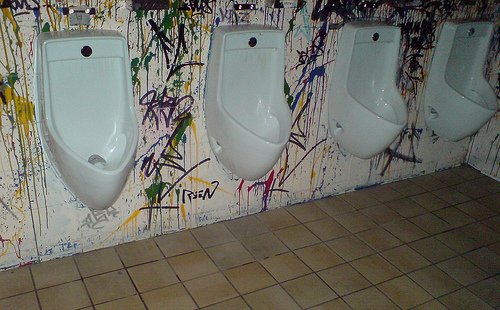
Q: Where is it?
A: This is at the restroom.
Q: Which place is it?
A: It is a restroom.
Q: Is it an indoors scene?
A: Yes, it is indoors.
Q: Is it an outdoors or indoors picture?
A: It is indoors.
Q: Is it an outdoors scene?
A: No, it is indoors.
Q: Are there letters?
A: Yes, there are letters.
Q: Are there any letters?
A: Yes, there are letters.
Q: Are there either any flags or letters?
A: Yes, there are letters.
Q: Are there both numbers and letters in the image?
A: No, there are letters but no numbers.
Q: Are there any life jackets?
A: No, there are no life jackets.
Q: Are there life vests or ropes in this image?
A: No, there are no life vests or ropes.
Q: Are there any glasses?
A: No, there are no glasses.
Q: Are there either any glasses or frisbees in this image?
A: No, there are no glasses or frisbees.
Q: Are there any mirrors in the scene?
A: No, there are no mirrors.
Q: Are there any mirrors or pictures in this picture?
A: No, there are no mirrors or pictures.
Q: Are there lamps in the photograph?
A: No, there are no lamps.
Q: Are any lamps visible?
A: No, there are no lamps.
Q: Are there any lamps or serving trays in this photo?
A: No, there are no lamps or serving trays.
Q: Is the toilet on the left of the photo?
A: Yes, the toilet is on the left of the image.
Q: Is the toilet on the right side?
A: No, the toilet is on the left of the image.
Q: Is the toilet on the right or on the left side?
A: The toilet is on the left of the image.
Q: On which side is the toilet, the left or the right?
A: The toilet is on the left of the image.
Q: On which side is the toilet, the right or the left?
A: The toilet is on the left of the image.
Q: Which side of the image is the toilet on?
A: The toilet is on the left of the image.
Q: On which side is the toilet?
A: The toilet is on the left of the image.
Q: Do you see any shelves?
A: No, there are no shelves.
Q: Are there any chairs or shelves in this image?
A: No, there are no shelves or chairs.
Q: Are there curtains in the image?
A: No, there are no curtains.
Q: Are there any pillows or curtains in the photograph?
A: No, there are no curtains or pillows.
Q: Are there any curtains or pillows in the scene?
A: No, there are no curtains or pillows.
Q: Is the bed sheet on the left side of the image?
A: Yes, the bed sheet is on the left of the image.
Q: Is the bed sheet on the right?
A: No, the bed sheet is on the left of the image.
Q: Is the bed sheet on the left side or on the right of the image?
A: The bed sheet is on the left of the image.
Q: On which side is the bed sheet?
A: The bed sheet is on the left of the image.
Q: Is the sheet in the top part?
A: Yes, the sheet is in the top of the image.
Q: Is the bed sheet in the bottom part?
A: No, the bed sheet is in the top of the image.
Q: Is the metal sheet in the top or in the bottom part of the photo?
A: The sheet is in the top of the image.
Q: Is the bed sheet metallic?
A: Yes, the bed sheet is metallic.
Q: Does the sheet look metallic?
A: Yes, the sheet is metallic.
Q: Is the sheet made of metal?
A: Yes, the sheet is made of metal.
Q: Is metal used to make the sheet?
A: Yes, the sheet is made of metal.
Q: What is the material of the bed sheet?
A: The bed sheet is made of metal.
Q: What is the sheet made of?
A: The bed sheet is made of metal.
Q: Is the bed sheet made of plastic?
A: No, the bed sheet is made of metal.